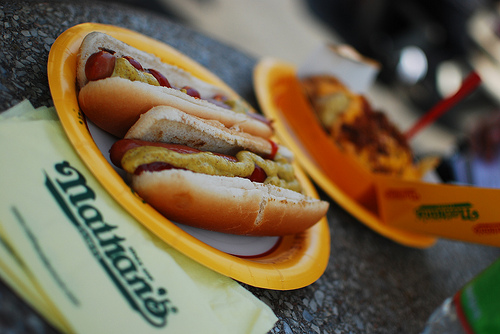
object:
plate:
[44, 21, 333, 295]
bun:
[78, 30, 276, 144]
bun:
[108, 104, 327, 236]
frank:
[106, 135, 301, 191]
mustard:
[122, 150, 305, 189]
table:
[5, 6, 499, 333]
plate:
[252, 56, 446, 251]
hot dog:
[109, 137, 304, 194]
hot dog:
[83, 50, 277, 133]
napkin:
[4, 94, 279, 334]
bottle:
[419, 260, 499, 332]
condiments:
[109, 44, 305, 195]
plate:
[48, 292, 330, 334]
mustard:
[109, 57, 160, 89]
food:
[294, 70, 421, 179]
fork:
[402, 61, 480, 141]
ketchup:
[105, 141, 304, 192]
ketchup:
[111, 51, 204, 97]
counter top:
[2, 0, 500, 334]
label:
[455, 265, 498, 332]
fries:
[298, 70, 440, 183]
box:
[254, 59, 500, 247]